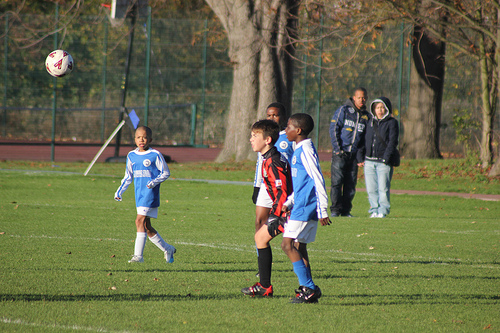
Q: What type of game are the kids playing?
A: Soccer.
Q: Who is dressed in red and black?
A: The child.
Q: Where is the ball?
A: In the air.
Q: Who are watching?
A: Spectators.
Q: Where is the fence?
A: Behind the players.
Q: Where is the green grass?
A: Soccer field.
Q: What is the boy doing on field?
A: Playing soccer.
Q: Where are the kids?
A: Park.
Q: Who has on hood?
A: A lady.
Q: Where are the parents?
A: Watching game.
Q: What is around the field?
A: Fence.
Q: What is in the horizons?
A: Trees.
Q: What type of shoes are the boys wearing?
A: Cleats.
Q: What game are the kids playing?
A: Soccer.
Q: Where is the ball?
A: In the air.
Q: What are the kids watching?
A: The ball.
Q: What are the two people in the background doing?
A: Watching the kids.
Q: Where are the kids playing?
A: Soccer field.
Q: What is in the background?
A: Trees.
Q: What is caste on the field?
A: Shadows.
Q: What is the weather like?
A: Sunny.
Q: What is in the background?
A: Basketball court.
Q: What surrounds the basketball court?
A: Fence.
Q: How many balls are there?
A: One.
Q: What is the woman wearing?
A: A coat.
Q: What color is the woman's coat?
A: Blue.